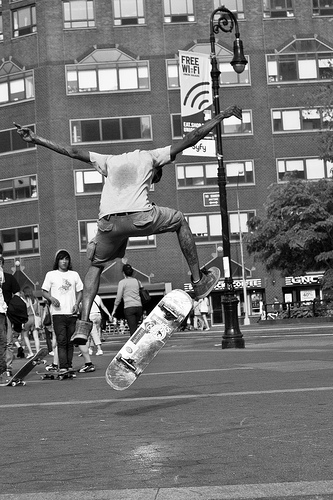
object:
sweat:
[109, 160, 140, 189]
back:
[99, 152, 149, 218]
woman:
[111, 262, 143, 337]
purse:
[136, 279, 152, 310]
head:
[56, 249, 73, 271]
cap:
[53, 246, 72, 263]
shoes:
[188, 266, 220, 304]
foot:
[58, 366, 67, 375]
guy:
[41, 248, 84, 371]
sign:
[202, 190, 220, 208]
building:
[0, 0, 332, 323]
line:
[0, 385, 333, 407]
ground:
[0, 321, 332, 499]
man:
[12, 103, 243, 345]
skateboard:
[103, 287, 194, 390]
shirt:
[88, 145, 176, 220]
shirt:
[39, 268, 85, 316]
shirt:
[113, 276, 143, 309]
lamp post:
[208, 6, 248, 351]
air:
[230, 321, 285, 381]